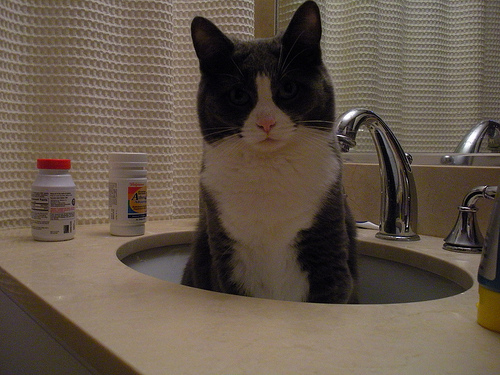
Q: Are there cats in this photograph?
A: Yes, there is a cat.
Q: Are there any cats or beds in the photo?
A: Yes, there is a cat.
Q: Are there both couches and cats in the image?
A: No, there is a cat but no couches.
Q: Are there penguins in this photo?
A: No, there are no penguins.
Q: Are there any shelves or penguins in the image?
A: No, there are no penguins or shelves.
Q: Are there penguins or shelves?
A: No, there are no penguins or shelves.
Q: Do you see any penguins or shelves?
A: No, there are no penguins or shelves.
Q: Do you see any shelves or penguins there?
A: No, there are no penguins or shelves.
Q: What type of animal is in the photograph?
A: The animal is a cat.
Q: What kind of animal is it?
A: The animal is a cat.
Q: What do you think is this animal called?
A: That is a cat.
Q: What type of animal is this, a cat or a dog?
A: That is a cat.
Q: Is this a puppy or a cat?
A: This is a cat.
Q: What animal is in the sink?
A: The cat is in the sink.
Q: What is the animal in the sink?
A: The animal is a cat.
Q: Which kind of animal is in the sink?
A: The animal is a cat.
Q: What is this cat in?
A: The cat is in the sink.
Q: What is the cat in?
A: The cat is in the sink.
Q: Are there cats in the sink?
A: Yes, there is a cat in the sink.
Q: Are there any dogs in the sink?
A: No, there is a cat in the sink.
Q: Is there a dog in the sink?
A: No, there is a cat in the sink.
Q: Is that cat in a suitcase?
A: No, the cat is in the sink.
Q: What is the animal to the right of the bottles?
A: The animal is a cat.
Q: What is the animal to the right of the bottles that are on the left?
A: The animal is a cat.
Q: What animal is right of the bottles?
A: The animal is a cat.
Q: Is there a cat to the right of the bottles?
A: Yes, there is a cat to the right of the bottles.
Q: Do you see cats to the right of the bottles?
A: Yes, there is a cat to the right of the bottles.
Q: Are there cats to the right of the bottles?
A: Yes, there is a cat to the right of the bottles.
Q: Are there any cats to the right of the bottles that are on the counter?
A: Yes, there is a cat to the right of the bottles.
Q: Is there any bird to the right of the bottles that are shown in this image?
A: No, there is a cat to the right of the bottles.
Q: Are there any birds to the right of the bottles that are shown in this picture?
A: No, there is a cat to the right of the bottles.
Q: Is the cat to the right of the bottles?
A: Yes, the cat is to the right of the bottles.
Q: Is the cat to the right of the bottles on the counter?
A: Yes, the cat is to the right of the bottles.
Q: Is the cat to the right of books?
A: No, the cat is to the right of the bottles.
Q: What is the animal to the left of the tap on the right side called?
A: The animal is a cat.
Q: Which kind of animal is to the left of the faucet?
A: The animal is a cat.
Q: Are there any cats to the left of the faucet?
A: Yes, there is a cat to the left of the faucet.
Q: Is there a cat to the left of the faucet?
A: Yes, there is a cat to the left of the faucet.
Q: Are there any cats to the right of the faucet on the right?
A: No, the cat is to the left of the faucet.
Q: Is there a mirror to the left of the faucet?
A: No, there is a cat to the left of the faucet.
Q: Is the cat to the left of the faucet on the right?
A: Yes, the cat is to the left of the faucet.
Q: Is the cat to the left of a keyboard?
A: No, the cat is to the left of the faucet.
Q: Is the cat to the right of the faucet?
A: No, the cat is to the left of the faucet.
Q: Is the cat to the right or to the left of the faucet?
A: The cat is to the left of the faucet.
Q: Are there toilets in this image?
A: No, there are no toilets.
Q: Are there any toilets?
A: No, there are no toilets.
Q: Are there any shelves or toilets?
A: No, there are no toilets or shelves.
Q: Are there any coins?
A: No, there are no coins.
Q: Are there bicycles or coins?
A: No, there are no coins or bicycles.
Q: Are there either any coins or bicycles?
A: No, there are no coins or bicycles.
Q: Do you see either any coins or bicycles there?
A: No, there are no coins or bicycles.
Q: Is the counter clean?
A: Yes, the counter is clean.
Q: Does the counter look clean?
A: Yes, the counter is clean.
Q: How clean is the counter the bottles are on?
A: The counter is clean.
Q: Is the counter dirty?
A: No, the counter is clean.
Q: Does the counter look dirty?
A: No, the counter is clean.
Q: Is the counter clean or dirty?
A: The counter is clean.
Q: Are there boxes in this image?
A: No, there are no boxes.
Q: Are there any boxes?
A: No, there are no boxes.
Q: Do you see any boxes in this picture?
A: No, there are no boxes.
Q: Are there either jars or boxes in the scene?
A: No, there are no boxes or jars.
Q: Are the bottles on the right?
A: No, the bottles are on the left of the image.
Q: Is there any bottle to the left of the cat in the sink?
A: Yes, there are bottles to the left of the cat.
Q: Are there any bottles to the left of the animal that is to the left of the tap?
A: Yes, there are bottles to the left of the cat.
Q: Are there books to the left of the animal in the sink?
A: No, there are bottles to the left of the cat.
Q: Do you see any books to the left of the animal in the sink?
A: No, there are bottles to the left of the cat.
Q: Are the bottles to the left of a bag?
A: No, the bottles are to the left of the cat.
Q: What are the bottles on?
A: The bottles are on the counter.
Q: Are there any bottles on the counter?
A: Yes, there are bottles on the counter.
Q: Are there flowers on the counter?
A: No, there are bottles on the counter.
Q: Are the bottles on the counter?
A: Yes, the bottles are on the counter.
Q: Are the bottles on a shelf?
A: No, the bottles are on the counter.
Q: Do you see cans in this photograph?
A: No, there are no cans.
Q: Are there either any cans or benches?
A: No, there are no cans or benches.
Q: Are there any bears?
A: No, there are no bears.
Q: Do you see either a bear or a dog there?
A: No, there are no bears or dogs.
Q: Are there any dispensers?
A: No, there are no dispensers.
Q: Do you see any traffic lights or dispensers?
A: No, there are no dispensers or traffic lights.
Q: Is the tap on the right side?
A: Yes, the tap is on the right of the image.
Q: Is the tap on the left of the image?
A: No, the tap is on the right of the image.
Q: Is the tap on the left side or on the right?
A: The tap is on the right of the image.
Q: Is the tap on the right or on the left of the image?
A: The tap is on the right of the image.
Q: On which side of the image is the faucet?
A: The faucet is on the right of the image.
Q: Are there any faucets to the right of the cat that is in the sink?
A: Yes, there is a faucet to the right of the cat.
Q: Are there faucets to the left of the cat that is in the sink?
A: No, the faucet is to the right of the cat.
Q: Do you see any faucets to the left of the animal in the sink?
A: No, the faucet is to the right of the cat.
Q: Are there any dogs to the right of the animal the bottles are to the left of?
A: No, there is a faucet to the right of the cat.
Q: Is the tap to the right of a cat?
A: Yes, the tap is to the right of a cat.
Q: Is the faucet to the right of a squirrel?
A: No, the faucet is to the right of a cat.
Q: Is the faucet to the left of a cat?
A: No, the faucet is to the right of a cat.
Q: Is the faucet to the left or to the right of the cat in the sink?
A: The faucet is to the right of the cat.